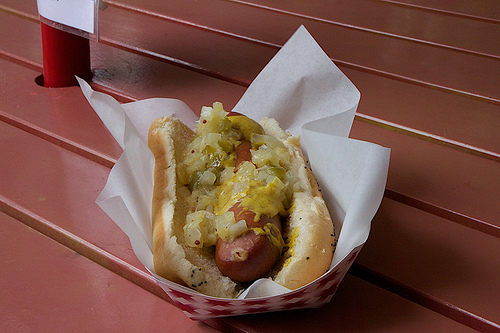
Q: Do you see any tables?
A: Yes, there is a table.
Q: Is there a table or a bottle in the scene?
A: Yes, there is a table.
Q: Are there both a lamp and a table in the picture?
A: No, there is a table but no lamps.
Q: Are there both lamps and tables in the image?
A: No, there is a table but no lamps.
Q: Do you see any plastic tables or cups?
A: Yes, there is a plastic table.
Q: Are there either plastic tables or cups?
A: Yes, there is a plastic table.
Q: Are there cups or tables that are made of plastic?
A: Yes, the table is made of plastic.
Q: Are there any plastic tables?
A: Yes, there is a table that is made of plastic.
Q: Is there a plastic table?
A: Yes, there is a table that is made of plastic.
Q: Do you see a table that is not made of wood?
A: Yes, there is a table that is made of plastic.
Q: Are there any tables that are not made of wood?
A: Yes, there is a table that is made of plastic.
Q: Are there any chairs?
A: No, there are no chairs.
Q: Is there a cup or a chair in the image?
A: No, there are no chairs or cups.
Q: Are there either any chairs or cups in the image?
A: No, there are no chairs or cups.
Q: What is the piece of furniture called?
A: The piece of furniture is a table.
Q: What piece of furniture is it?
A: The piece of furniture is a table.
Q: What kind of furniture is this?
A: This is a table.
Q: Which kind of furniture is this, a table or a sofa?
A: This is a table.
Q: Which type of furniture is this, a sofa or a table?
A: This is a table.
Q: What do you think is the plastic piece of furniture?
A: The piece of furniture is a table.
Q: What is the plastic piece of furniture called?
A: The piece of furniture is a table.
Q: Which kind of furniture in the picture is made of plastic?
A: The furniture is a table.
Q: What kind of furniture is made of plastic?
A: The furniture is a table.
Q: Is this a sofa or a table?
A: This is a table.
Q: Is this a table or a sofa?
A: This is a table.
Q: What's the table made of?
A: The table is made of plastic.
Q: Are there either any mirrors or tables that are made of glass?
A: No, there is a table but it is made of plastic.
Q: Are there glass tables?
A: No, there is a table but it is made of plastic.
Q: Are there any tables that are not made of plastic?
A: No, there is a table but it is made of plastic.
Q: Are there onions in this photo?
A: Yes, there are onions.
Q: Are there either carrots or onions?
A: Yes, there are onions.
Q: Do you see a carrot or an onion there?
A: Yes, there are onions.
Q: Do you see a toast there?
A: No, there are no toasts.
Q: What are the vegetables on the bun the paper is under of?
A: The vegetables are onions.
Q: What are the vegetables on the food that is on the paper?
A: The vegetables are onions.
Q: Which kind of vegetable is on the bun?
A: The vegetables are onions.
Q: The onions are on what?
A: The onions are on the bun.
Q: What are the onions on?
A: The onions are on the bun.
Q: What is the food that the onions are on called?
A: The food is a bun.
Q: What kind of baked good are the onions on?
A: The onions are on the bun.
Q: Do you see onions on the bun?
A: Yes, there are onions on the bun.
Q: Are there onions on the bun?
A: Yes, there are onions on the bun.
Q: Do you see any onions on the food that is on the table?
A: Yes, there are onions on the bun.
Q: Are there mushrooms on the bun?
A: No, there are onions on the bun.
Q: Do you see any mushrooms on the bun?
A: No, there are onions on the bun.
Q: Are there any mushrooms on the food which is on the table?
A: No, there are onions on the bun.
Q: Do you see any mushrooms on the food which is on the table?
A: No, there are onions on the bun.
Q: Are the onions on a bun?
A: Yes, the onions are on a bun.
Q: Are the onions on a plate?
A: No, the onions are on a bun.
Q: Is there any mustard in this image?
A: Yes, there is mustard.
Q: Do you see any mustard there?
A: Yes, there is mustard.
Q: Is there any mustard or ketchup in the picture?
A: Yes, there is mustard.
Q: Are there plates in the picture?
A: No, there are no plates.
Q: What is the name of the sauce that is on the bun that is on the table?
A: The sauce is mustard.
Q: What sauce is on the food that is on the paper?
A: The sauce is mustard.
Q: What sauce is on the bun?
A: The sauce is mustard.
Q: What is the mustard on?
A: The mustard is on the bun.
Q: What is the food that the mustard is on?
A: The food is a bun.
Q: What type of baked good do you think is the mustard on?
A: The mustard is on the bun.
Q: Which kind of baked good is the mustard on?
A: The mustard is on the bun.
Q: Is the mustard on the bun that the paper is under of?
A: Yes, the mustard is on the bun.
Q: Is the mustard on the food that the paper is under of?
A: Yes, the mustard is on the bun.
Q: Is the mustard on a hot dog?
A: No, the mustard is on the bun.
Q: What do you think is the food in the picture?
A: The food is a bun.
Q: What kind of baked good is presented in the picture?
A: The baked good is a bun.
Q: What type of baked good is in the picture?
A: The baked good is a bun.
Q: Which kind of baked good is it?
A: The food is a bun.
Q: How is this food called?
A: This is a bun.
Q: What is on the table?
A: The bun is on the table.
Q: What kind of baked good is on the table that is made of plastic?
A: The food is a bun.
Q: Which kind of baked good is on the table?
A: The food is a bun.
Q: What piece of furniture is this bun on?
A: The bun is on the table.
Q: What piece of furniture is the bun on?
A: The bun is on the table.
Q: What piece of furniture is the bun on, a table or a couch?
A: The bun is on a table.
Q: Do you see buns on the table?
A: Yes, there is a bun on the table.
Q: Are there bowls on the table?
A: No, there is a bun on the table.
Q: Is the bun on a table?
A: Yes, the bun is on a table.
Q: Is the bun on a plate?
A: No, the bun is on a table.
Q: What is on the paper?
A: The bun is on the paper.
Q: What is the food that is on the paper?
A: The food is a bun.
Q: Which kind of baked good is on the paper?
A: The food is a bun.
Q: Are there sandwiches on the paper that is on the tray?
A: No, there is a bun on the paper.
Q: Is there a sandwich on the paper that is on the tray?
A: No, there is a bun on the paper.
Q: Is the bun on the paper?
A: Yes, the bun is on the paper.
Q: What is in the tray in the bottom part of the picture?
A: The bun is in the tray.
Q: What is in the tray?
A: The bun is in the tray.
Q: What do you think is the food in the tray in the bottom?
A: The food is a bun.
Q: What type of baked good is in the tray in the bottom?
A: The food is a bun.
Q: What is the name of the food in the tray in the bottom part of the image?
A: The food is a bun.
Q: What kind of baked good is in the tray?
A: The food is a bun.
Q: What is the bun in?
A: The bun is in the tray.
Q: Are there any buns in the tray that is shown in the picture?
A: Yes, there is a bun in the tray.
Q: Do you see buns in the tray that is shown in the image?
A: Yes, there is a bun in the tray.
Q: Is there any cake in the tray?
A: No, there is a bun in the tray.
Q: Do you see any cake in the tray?
A: No, there is a bun in the tray.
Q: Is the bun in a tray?
A: Yes, the bun is in a tray.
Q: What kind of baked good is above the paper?
A: The food is a bun.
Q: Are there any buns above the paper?
A: Yes, there is a bun above the paper.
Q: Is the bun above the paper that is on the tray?
A: Yes, the bun is above the paper.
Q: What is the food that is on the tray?
A: The food is a bun.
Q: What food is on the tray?
A: The food is a bun.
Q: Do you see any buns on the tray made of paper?
A: Yes, there is a bun on the tray.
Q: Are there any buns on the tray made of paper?
A: Yes, there is a bun on the tray.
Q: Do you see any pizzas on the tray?
A: No, there is a bun on the tray.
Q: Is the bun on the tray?
A: Yes, the bun is on the tray.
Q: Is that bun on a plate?
A: No, the bun is on the tray.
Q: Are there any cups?
A: No, there are no cups.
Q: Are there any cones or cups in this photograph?
A: No, there are no cups or cones.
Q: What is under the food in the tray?
A: The paper is under the bun.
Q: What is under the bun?
A: The paper is under the bun.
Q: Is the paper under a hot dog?
A: No, the paper is under the bun.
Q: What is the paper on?
A: The paper is on the tray.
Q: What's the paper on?
A: The paper is on the tray.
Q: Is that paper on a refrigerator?
A: No, the paper is on a tray.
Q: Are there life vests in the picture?
A: No, there are no life vests.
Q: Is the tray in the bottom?
A: Yes, the tray is in the bottom of the image.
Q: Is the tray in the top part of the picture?
A: No, the tray is in the bottom of the image.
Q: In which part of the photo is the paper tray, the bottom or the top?
A: The tray is in the bottom of the image.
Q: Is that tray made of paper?
A: Yes, the tray is made of paper.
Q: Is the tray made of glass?
A: No, the tray is made of paper.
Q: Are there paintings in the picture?
A: No, there are no paintings.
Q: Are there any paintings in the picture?
A: No, there are no paintings.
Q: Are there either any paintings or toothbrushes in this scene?
A: No, there are no paintings or toothbrushes.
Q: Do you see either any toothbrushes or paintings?
A: No, there are no paintings or toothbrushes.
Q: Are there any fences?
A: No, there are no fences.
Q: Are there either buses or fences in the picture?
A: No, there are no fences or buses.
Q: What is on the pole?
A: The sign is on the pole.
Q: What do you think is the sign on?
A: The sign is on the pole.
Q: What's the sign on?
A: The sign is on the pole.